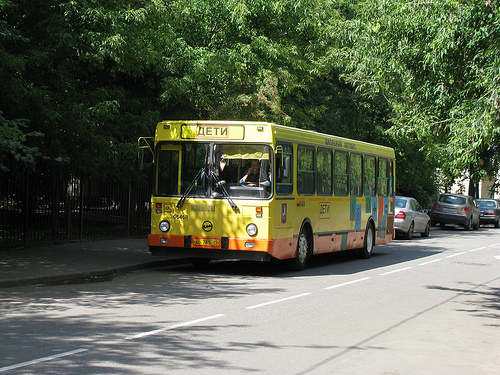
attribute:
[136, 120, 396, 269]
bus — yellow, orange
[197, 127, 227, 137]
lettering — black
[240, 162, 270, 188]
person — driving, driver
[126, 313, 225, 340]
line — white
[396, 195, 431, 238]
car — parked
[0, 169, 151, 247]
fence — black, metal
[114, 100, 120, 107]
leaf — green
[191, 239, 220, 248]
plate — yellow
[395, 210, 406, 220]
light — red